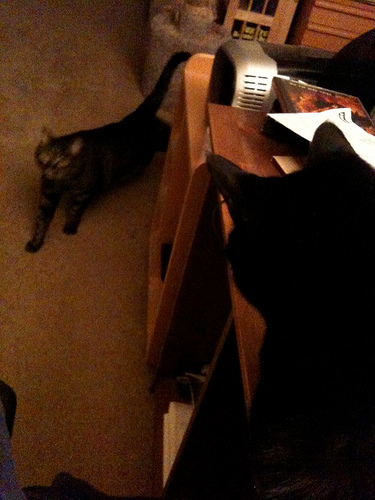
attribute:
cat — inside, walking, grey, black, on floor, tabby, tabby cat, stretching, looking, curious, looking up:
[23, 53, 202, 251]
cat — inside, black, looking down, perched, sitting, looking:
[187, 136, 374, 499]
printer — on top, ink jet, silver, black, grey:
[209, 37, 340, 106]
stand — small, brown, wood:
[144, 50, 226, 363]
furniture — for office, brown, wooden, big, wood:
[143, 105, 267, 494]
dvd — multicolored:
[274, 70, 375, 136]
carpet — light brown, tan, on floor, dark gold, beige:
[8, 49, 169, 494]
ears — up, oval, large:
[200, 153, 268, 213]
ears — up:
[303, 120, 357, 160]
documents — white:
[156, 397, 189, 484]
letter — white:
[267, 106, 369, 165]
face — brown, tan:
[31, 129, 83, 180]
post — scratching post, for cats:
[144, 0, 232, 97]